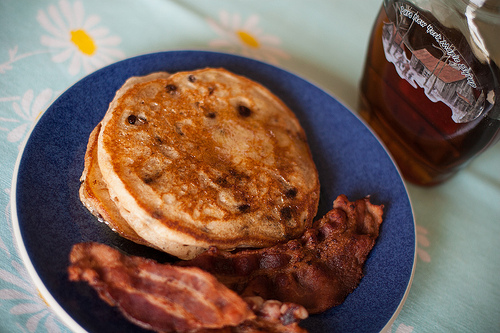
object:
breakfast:
[62, 62, 392, 332]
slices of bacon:
[149, 196, 387, 314]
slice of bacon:
[61, 239, 306, 332]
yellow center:
[188, 118, 240, 164]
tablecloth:
[0, 0, 498, 332]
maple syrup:
[358, 0, 500, 188]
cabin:
[405, 47, 469, 106]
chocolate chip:
[237, 105, 251, 117]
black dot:
[128, 115, 137, 124]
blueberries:
[187, 74, 197, 83]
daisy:
[32, 0, 132, 74]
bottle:
[350, 0, 498, 189]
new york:
[412, 13, 442, 41]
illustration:
[378, 12, 482, 112]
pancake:
[75, 67, 322, 257]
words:
[392, 1, 428, 27]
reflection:
[448, 2, 484, 47]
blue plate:
[16, 49, 416, 333]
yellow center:
[70, 29, 99, 55]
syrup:
[355, 2, 500, 184]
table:
[0, 0, 500, 333]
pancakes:
[100, 59, 349, 281]